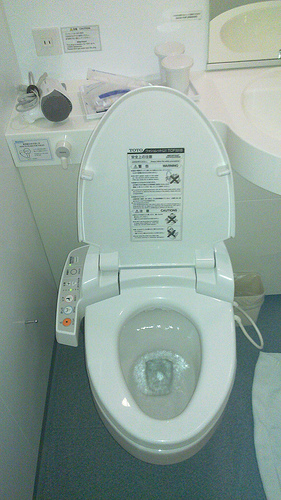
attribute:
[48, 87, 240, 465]
toilet — behind 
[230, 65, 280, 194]
sink — small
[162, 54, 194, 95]
cup — specimen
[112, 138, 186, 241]
chart — attached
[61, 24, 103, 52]
sign — small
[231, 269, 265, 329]
trash can — small, brown